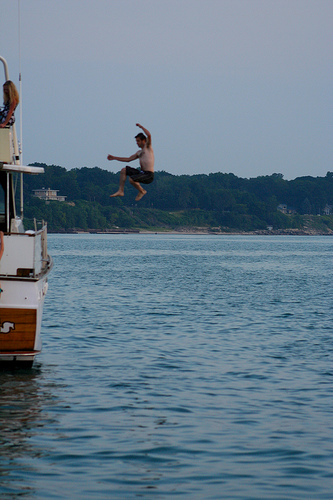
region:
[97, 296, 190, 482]
the water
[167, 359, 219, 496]
the water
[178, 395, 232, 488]
the water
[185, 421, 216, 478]
the water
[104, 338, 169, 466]
the water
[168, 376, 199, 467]
the water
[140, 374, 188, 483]
the water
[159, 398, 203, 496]
the water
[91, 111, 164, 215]
person is jumping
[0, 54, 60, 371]
a white and red boat in the ocean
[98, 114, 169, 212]
person wears black pants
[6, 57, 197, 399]
person is jumping from a boat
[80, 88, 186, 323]
person is jumping in the sea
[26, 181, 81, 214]
a home on a hill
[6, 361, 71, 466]
reflection of boat in the water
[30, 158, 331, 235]
trees in the shore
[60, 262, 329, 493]
water of sea has ripples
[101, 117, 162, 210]
man hands on side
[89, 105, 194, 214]
man jumped off boat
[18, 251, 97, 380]
boat is white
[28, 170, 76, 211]
house above the water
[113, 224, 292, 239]
shoreline along the water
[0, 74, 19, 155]
woman sitting on boat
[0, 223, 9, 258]
person on the back of boat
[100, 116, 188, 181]
man's arms are in the air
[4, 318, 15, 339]
white s on back of boat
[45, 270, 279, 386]
water is calm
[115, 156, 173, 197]
man's bathing suit is black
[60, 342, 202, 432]
clear blue water on bottom of photo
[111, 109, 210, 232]
man in mid air above water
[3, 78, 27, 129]
blonde woman on upper level of boat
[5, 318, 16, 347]
letter s on back side of boat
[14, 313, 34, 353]
wood grain on back of boat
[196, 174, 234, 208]
green trees on hillside in back of photo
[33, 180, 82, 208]
multilevel house in the distance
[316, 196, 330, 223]
2 story house to the right of trees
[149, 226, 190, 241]
brown sandy beach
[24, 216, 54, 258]
boat rail on right side of boat